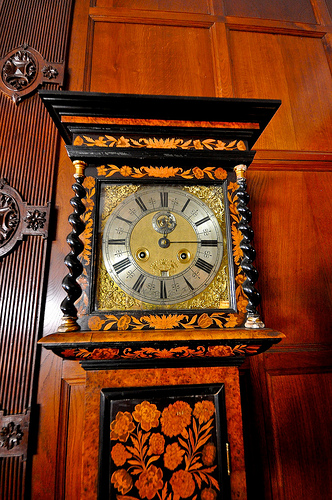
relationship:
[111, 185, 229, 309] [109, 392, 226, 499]
clock has design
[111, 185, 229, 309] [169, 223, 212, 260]
clock has hands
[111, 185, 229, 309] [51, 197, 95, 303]
clock has spiral